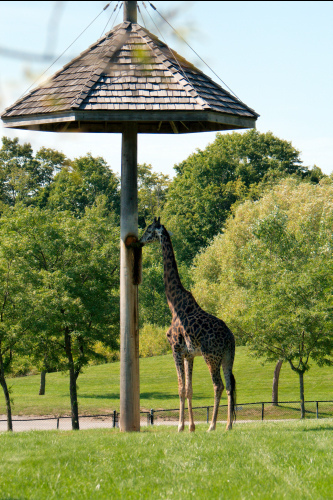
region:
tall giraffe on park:
[138, 217, 239, 432]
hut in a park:
[3, 2, 257, 429]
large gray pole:
[118, 121, 141, 431]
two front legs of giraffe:
[172, 352, 198, 430]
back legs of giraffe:
[205, 360, 236, 432]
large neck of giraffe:
[158, 228, 184, 296]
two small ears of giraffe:
[152, 215, 161, 225]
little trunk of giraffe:
[141, 229, 151, 246]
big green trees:
[1, 137, 332, 423]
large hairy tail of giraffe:
[228, 364, 238, 420]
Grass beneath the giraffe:
[1, 419, 329, 499]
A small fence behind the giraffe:
[0, 400, 331, 431]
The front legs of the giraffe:
[173, 356, 196, 433]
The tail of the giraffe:
[230, 361, 238, 419]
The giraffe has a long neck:
[161, 230, 180, 294]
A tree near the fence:
[249, 221, 332, 419]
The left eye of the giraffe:
[146, 227, 150, 234]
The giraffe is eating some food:
[140, 218, 236, 432]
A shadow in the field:
[73, 392, 217, 400]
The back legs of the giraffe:
[204, 354, 234, 431]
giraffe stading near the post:
[123, 203, 246, 430]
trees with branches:
[191, 152, 322, 358]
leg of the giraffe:
[172, 372, 238, 436]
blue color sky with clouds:
[230, 16, 299, 85]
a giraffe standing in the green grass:
[59, 168, 253, 498]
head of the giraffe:
[116, 211, 180, 261]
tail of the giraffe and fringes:
[229, 348, 243, 430]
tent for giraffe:
[10, 40, 256, 129]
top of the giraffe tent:
[32, 14, 224, 116]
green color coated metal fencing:
[239, 402, 331, 424]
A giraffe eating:
[132, 212, 247, 442]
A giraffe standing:
[115, 216, 260, 443]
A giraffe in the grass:
[129, 209, 269, 445]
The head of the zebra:
[136, 216, 168, 248]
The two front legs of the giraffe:
[171, 349, 202, 435]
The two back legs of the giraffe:
[203, 354, 242, 438]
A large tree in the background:
[187, 233, 332, 419]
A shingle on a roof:
[135, 102, 144, 111]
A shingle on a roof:
[176, 103, 184, 109]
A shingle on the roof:
[120, 57, 126, 63]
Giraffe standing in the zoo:
[142, 219, 254, 447]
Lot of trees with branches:
[215, 154, 307, 288]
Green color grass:
[54, 444, 272, 483]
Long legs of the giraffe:
[175, 371, 220, 442]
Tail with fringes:
[230, 371, 243, 423]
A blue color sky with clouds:
[240, 20, 312, 75]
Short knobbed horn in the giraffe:
[151, 212, 165, 221]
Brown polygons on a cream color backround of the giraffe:
[182, 313, 218, 341]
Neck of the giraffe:
[160, 250, 182, 289]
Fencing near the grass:
[254, 402, 327, 419]